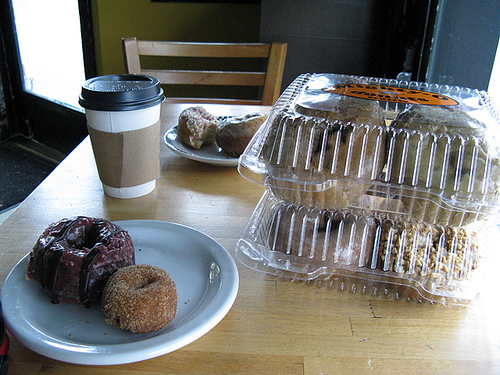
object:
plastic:
[235, 72, 499, 317]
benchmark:
[368, 299, 382, 318]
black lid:
[78, 73, 167, 112]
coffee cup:
[77, 72, 168, 198]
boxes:
[236, 73, 499, 309]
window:
[0, 0, 94, 113]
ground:
[433, 149, 455, 169]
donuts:
[269, 206, 484, 300]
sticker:
[322, 83, 460, 106]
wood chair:
[124, 32, 290, 104]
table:
[0, 102, 500, 374]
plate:
[163, 112, 273, 167]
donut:
[178, 106, 218, 150]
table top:
[0, 102, 499, 374]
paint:
[92, 0, 267, 110]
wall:
[1, 1, 498, 170]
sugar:
[133, 293, 149, 304]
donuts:
[27, 216, 178, 336]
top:
[123, 39, 287, 68]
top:
[79, 74, 168, 111]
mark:
[348, 317, 354, 337]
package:
[231, 71, 499, 312]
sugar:
[42, 217, 121, 267]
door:
[3, 0, 96, 166]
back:
[125, 36, 287, 107]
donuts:
[263, 88, 499, 305]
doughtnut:
[213, 113, 268, 157]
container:
[238, 72, 498, 227]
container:
[235, 184, 500, 309]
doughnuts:
[267, 83, 500, 228]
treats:
[26, 214, 177, 333]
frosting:
[30, 216, 128, 301]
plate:
[0, 219, 239, 367]